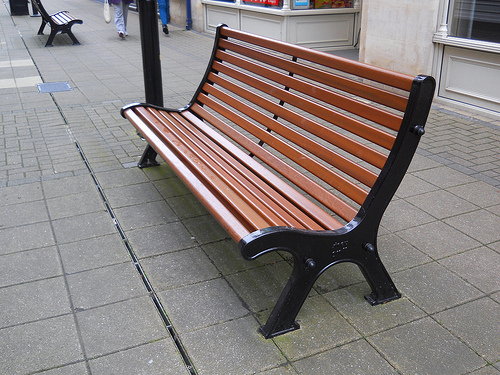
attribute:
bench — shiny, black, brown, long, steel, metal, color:
[114, 19, 462, 300]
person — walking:
[82, 1, 185, 54]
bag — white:
[90, 4, 117, 38]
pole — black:
[106, 5, 176, 141]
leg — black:
[225, 215, 437, 357]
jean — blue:
[144, 2, 180, 46]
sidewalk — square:
[28, 22, 242, 237]